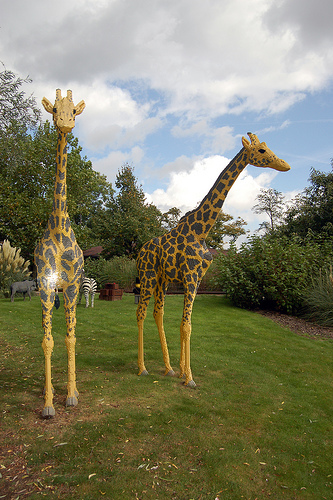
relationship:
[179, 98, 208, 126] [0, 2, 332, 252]
cloud in sky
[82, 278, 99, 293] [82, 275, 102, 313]
butt of zebra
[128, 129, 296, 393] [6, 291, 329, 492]
giraffe on grass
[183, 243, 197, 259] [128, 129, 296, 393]
spot on giraffe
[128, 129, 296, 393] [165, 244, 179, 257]
giraffe has spot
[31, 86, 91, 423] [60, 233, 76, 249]
giraffe has spot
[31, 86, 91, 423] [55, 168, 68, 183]
giraffe has spot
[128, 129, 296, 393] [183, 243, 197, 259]
giraffe has spot